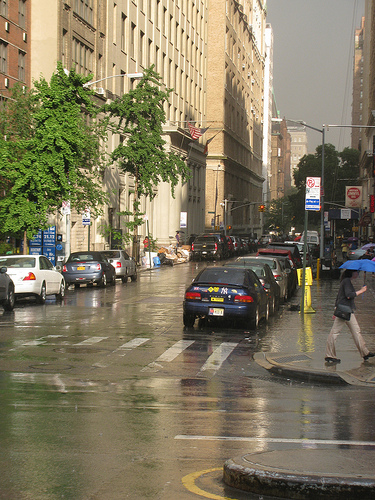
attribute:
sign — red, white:
[305, 176, 320, 209]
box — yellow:
[294, 257, 331, 321]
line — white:
[196, 340, 239, 377]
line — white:
[138, 338, 195, 372]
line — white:
[92, 335, 152, 367]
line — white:
[72, 334, 109, 346]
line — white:
[7, 331, 64, 351]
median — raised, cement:
[218, 431, 344, 497]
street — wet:
[138, 270, 183, 327]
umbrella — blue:
[332, 255, 373, 275]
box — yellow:
[293, 265, 310, 310]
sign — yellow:
[299, 264, 319, 318]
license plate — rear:
[205, 304, 228, 320]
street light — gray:
[271, 113, 322, 141]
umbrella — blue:
[344, 255, 374, 271]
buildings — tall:
[1, 1, 309, 236]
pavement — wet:
[2, 248, 367, 498]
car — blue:
[184, 266, 276, 334]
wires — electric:
[331, 5, 358, 148]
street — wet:
[5, 247, 362, 496]